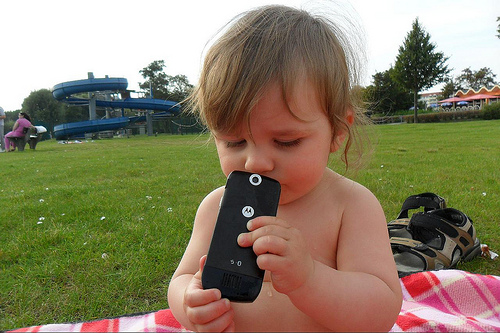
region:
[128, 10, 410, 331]
a child holding a smartphone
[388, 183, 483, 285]
a pair of tan sandals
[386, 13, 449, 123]
a small conifer tree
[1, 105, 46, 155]
a woman in pink sitting on a bench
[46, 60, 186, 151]
a water slide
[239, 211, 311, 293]
the hand of a child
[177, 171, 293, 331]
the hands of a child holding a smartphone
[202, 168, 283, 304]
the back of a cellphone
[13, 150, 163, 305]
The grass short and green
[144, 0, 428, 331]
The baby has a cell phone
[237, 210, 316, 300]
The hand of the cell phone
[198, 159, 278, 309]
The phone is the color black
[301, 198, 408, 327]
The arm of the baby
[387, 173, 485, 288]
The shoes on the ground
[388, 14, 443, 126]
The tree in the park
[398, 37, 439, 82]
The leaves of the tree are green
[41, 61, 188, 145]
The slide is the color blue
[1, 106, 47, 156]
A person sitting on the bench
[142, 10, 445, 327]
this is a baby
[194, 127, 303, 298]
the cell phone is black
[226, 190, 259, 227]
silver emblem on phone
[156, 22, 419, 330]
baby not wearing a shirt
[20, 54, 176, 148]
blue side in background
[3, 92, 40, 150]
woman sitting on a bench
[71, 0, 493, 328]
baby sitting on a blanket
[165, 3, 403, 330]
a baby holding a black cell phone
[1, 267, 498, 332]
a red and white checkered blanket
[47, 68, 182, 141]
an enclosed blue water slide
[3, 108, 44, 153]
a lady wearing pink and sitting on a bench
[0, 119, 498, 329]
a large area of green grass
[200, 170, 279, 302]
a black motorola cell phone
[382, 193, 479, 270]
black, brown, and tan sandles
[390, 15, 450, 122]
a tall green tree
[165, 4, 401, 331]
a young child with brown hair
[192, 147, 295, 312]
this is a cell phone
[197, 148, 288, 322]
the cell phone is black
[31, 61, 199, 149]
this is a water slid e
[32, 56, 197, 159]
this is a blue water slide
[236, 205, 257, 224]
this is the Motorola logo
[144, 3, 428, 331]
the child is holding the phone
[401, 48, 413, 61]
green leaves on the tree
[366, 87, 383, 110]
green leaves on the tree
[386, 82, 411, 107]
green leaves on the tree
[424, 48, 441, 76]
green leaves on the tree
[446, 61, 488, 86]
green leaves on the tree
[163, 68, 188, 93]
green leaves on the tree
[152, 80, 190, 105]
green leaves on the tree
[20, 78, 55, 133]
green leaves on the tree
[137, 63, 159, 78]
green leaves on the tree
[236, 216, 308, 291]
Hand of a girl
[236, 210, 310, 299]
Hand of a girl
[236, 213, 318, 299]
Hand of a girl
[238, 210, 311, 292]
Hand of a girl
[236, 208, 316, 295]
Hand of a girl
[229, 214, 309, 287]
Hand of a girl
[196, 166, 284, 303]
black cell phone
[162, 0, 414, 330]
baby holding black cell phone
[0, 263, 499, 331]
red and white plaid picnic blanket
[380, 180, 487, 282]
olive colored sandals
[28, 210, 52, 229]
whtie flowers in green field